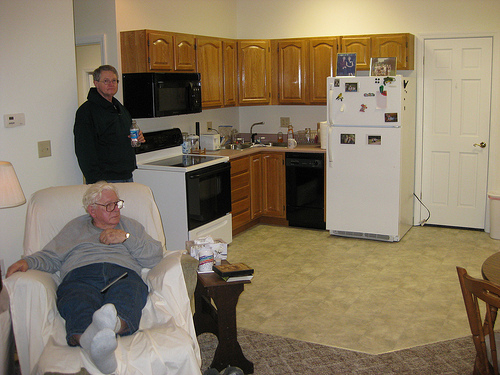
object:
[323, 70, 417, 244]
refrigerator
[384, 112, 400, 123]
magnets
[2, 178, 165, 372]
man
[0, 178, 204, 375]
recliner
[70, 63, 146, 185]
man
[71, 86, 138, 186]
jacket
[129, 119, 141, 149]
beverage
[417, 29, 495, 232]
door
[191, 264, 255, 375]
table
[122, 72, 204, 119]
microwave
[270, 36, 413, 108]
cupboards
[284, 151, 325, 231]
dishwasher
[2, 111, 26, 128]
thermostat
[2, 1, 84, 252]
wall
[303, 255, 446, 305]
tile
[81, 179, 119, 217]
hair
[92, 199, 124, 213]
glasses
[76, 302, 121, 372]
socks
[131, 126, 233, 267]
range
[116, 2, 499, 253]
kitchen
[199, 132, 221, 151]
toaster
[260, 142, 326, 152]
counter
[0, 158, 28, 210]
lampshade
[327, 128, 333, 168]
handle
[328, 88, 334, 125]
handle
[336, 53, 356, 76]
picture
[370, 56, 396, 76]
picture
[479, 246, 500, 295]
table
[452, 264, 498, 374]
chair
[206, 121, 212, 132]
outlet